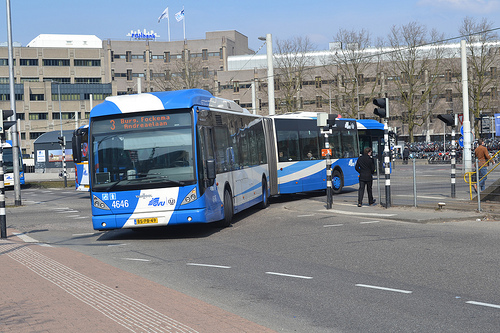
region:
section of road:
[316, 238, 350, 265]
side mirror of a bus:
[210, 166, 217, 179]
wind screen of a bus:
[109, 138, 139, 164]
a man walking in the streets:
[357, 150, 373, 194]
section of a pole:
[16, 137, 20, 179]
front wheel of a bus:
[228, 197, 233, 212]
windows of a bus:
[214, 146, 251, 159]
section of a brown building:
[47, 106, 61, 114]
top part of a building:
[147, 92, 175, 104]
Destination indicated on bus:
[60, 78, 243, 176]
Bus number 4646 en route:
[75, 151, 271, 273]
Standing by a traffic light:
[349, 80, 426, 220]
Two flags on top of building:
[107, 0, 267, 59]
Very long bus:
[44, 56, 464, 276]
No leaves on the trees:
[258, 13, 499, 183]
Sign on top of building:
[112, 12, 184, 56]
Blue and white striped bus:
[63, 70, 286, 264]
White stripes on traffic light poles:
[303, 92, 427, 232]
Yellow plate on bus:
[116, 201, 184, 242]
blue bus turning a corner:
[85, 75, 390, 233]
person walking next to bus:
[350, 141, 377, 213]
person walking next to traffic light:
[350, 140, 382, 208]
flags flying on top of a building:
[151, 3, 194, 36]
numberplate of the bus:
[123, 211, 166, 229]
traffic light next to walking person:
[366, 91, 407, 207]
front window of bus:
[85, 100, 220, 200]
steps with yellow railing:
[460, 132, 495, 199]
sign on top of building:
[125, 25, 161, 40]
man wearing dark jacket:
[350, 141, 395, 211]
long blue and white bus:
[91, 87, 397, 224]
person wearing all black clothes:
[353, 137, 386, 208]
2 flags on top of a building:
[156, 2, 197, 52]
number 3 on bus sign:
[105, 112, 185, 135]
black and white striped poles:
[323, 113, 470, 210]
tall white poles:
[441, 29, 494, 179]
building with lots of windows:
[4, 39, 248, 97]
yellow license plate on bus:
[129, 214, 166, 230]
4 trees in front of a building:
[277, 35, 499, 133]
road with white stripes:
[137, 233, 492, 330]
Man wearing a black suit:
[353, 141, 378, 209]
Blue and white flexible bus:
[65, 82, 365, 236]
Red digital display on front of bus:
[82, 105, 196, 137]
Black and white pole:
[376, 125, 396, 205]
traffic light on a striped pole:
[370, 90, 400, 210]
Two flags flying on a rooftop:
[141, 1, 182, 36]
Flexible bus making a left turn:
[60, 75, 360, 315]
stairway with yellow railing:
[461, 149, 499, 201]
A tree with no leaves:
[380, 15, 440, 160]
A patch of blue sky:
[5, 0, 415, 31]